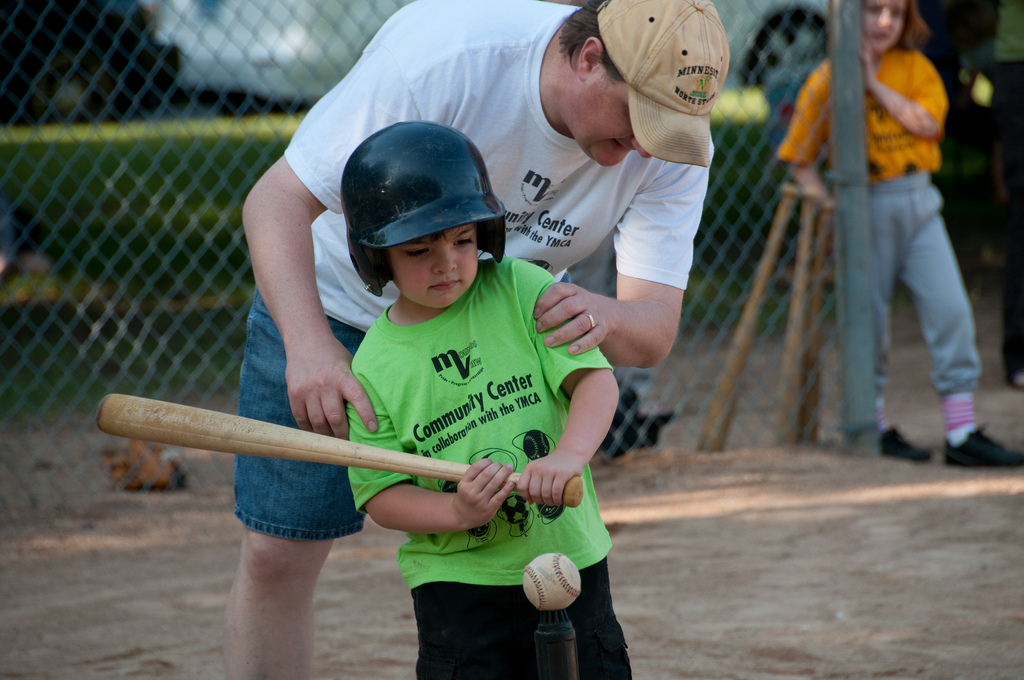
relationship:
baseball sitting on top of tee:
[515, 549, 585, 614] [530, 610, 580, 677]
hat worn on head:
[593, 1, 730, 172] [554, 1, 734, 170]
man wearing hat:
[215, 3, 730, 676] [593, 1, 730, 172]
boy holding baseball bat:
[338, 117, 632, 677] [94, 389, 585, 510]